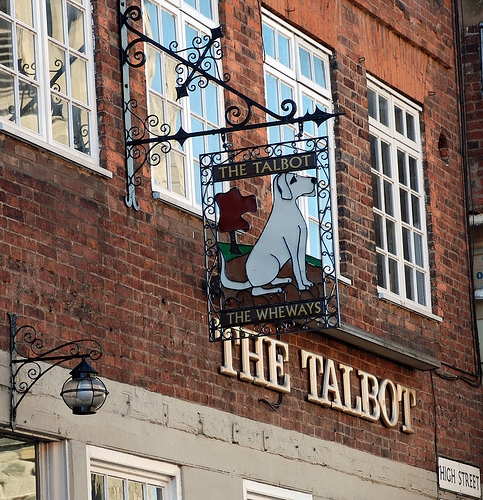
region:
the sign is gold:
[180, 316, 422, 452]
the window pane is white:
[342, 71, 448, 324]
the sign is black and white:
[424, 450, 481, 498]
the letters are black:
[434, 462, 477, 488]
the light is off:
[26, 322, 164, 429]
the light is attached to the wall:
[2, 311, 150, 429]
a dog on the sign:
[218, 140, 347, 295]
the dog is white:
[218, 145, 332, 298]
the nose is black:
[303, 171, 322, 193]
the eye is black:
[278, 169, 300, 189]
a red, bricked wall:
[45, 206, 166, 338]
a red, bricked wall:
[437, 120, 468, 320]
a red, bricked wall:
[70, 269, 194, 365]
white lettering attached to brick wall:
[211, 324, 414, 437]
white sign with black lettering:
[438, 457, 482, 498]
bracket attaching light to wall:
[2, 300, 68, 428]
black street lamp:
[57, 361, 112, 412]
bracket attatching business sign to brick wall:
[116, 7, 334, 151]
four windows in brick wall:
[0, 2, 438, 320]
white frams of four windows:
[2, 2, 444, 304]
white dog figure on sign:
[215, 164, 312, 295]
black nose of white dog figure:
[307, 174, 318, 183]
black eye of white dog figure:
[286, 177, 297, 183]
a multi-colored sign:
[192, 137, 343, 347]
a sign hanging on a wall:
[125, 19, 343, 351]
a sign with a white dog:
[189, 132, 349, 345]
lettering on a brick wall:
[206, 324, 425, 436]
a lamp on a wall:
[9, 322, 109, 428]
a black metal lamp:
[6, 317, 111, 436]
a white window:
[359, 67, 443, 327]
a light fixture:
[7, 318, 114, 442]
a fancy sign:
[113, 4, 347, 339]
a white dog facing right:
[215, 167, 331, 294]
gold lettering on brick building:
[207, 328, 433, 430]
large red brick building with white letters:
[46, 29, 435, 306]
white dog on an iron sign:
[193, 107, 347, 341]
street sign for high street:
[427, 453, 482, 493]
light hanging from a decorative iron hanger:
[4, 298, 112, 427]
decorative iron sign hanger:
[116, 5, 351, 214]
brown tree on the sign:
[217, 177, 263, 268]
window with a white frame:
[360, 83, 442, 311]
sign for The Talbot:
[193, 121, 350, 346]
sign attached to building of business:
[115, 100, 368, 347]